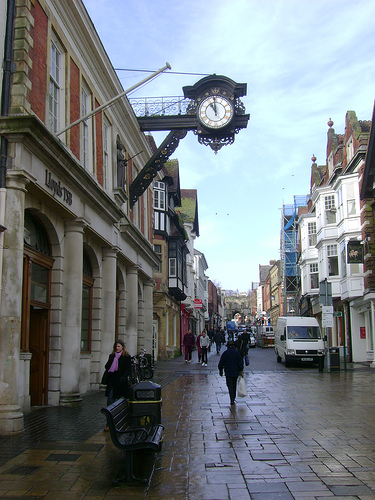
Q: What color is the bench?
A: Black.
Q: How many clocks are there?
A: One.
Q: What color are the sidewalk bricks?
A: Brown.